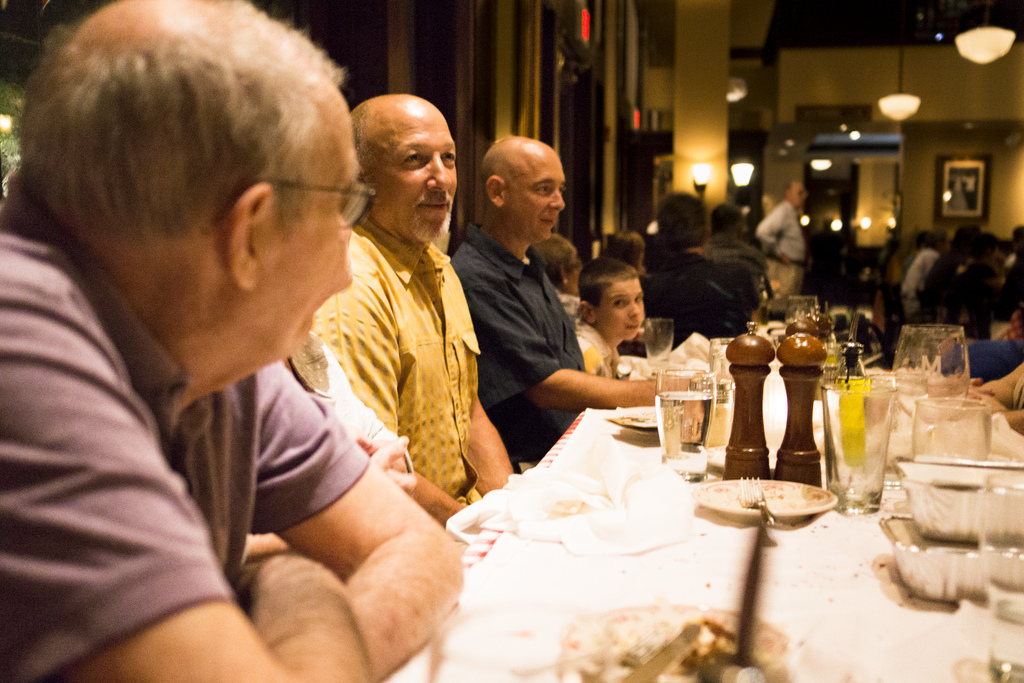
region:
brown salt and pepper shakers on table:
[734, 320, 827, 486]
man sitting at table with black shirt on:
[476, 133, 568, 393]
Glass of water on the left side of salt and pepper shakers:
[643, 361, 721, 480]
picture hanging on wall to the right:
[936, 142, 995, 220]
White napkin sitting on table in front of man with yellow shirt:
[490, 456, 678, 555]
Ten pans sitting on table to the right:
[854, 455, 1014, 582]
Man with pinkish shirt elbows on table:
[332, 503, 462, 652]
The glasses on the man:
[254, 169, 384, 220]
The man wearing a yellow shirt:
[330, 92, 528, 508]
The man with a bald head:
[311, 98, 545, 514]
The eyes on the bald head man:
[396, 145, 467, 169]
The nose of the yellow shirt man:
[418, 155, 454, 193]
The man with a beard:
[314, 102, 539, 536]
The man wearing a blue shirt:
[453, 114, 698, 454]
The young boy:
[562, 256, 662, 380]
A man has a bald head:
[333, 81, 466, 256]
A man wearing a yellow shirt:
[291, 80, 526, 529]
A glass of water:
[637, 345, 726, 466]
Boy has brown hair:
[563, 247, 655, 352]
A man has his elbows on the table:
[0, 1, 475, 675]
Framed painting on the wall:
[917, 143, 1006, 235]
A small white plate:
[680, 460, 848, 534]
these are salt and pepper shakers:
[719, 310, 844, 510]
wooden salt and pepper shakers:
[699, 271, 846, 505]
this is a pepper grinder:
[719, 304, 776, 478]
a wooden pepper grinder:
[700, 298, 780, 488]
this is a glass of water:
[643, 338, 723, 476]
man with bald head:
[481, 134, 589, 249]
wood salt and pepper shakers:
[725, 320, 823, 477]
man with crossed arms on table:
[1, 2, 461, 679]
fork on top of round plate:
[693, 476, 837, 524]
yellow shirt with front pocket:
[332, 221, 479, 498]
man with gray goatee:
[354, 92, 456, 244]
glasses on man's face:
[25, 2, 371, 395]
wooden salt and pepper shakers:
[726, 318, 825, 486]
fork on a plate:
[699, 476, 833, 530]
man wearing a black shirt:
[470, 132, 607, 466]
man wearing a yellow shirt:
[341, 91, 482, 524]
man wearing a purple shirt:
[10, 50, 372, 679]